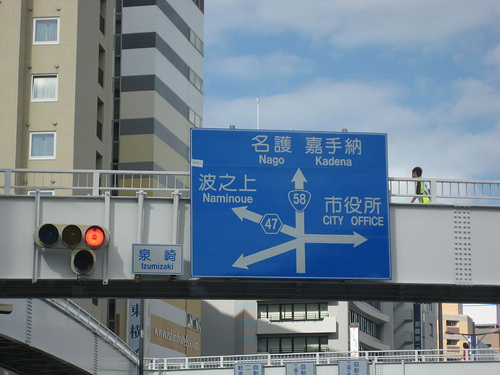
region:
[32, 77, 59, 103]
the window of a building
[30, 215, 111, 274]
a streetlight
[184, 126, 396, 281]
a large blue street sign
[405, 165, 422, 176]
the head of a man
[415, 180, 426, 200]
a yellow jacket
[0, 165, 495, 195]
a long white rail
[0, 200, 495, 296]
a long walking bridge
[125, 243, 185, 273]
a small blue and white sign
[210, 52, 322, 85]
a white cloud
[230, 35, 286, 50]
part of the blue sky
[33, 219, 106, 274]
a 4 way traffic signal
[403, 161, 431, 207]
a boy in a yellow shirt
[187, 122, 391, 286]
a blue and white traffic sign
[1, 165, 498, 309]
a white street overpass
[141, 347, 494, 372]
a white street overpass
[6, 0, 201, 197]
a tall brown building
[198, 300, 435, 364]
a tall white building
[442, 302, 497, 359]
a tall brown building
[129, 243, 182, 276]
a white and blue traffic sign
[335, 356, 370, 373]
a white and blue traffic sign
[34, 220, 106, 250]
traffic light laid out horizontally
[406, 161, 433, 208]
person walking across bridge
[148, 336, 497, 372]
footbridge in the distance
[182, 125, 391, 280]
sign with directional information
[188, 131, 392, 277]
a bi-lingual traffic sign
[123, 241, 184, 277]
small white and blue sign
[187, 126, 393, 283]
large blue and white sign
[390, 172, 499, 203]
metal rail on footbridge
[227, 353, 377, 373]
three similar traffic signs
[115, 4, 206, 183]
building with windows that will not open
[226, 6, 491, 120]
white clouds against blue sky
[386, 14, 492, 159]
white clouds against blue sky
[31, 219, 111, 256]
gray signal light on bridge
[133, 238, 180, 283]
blue and white sign on bridge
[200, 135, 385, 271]
blue and white sign on bridge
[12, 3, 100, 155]
windows in brown and white building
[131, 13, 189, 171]
windows in brown and white building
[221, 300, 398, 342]
windows in gray building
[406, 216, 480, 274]
gray supporting structure of bridge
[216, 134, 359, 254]
blue and white directional sign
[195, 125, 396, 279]
sign is blue with white letters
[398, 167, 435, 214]
person walking on bridge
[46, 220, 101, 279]
traffic light is showing red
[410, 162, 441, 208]
person wearing yellow shirt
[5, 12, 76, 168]
3 windows in tan building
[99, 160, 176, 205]
metal railing on bridge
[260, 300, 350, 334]
balcony outside gray building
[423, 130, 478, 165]
sky is blue with white clouds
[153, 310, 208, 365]
words on building in asian